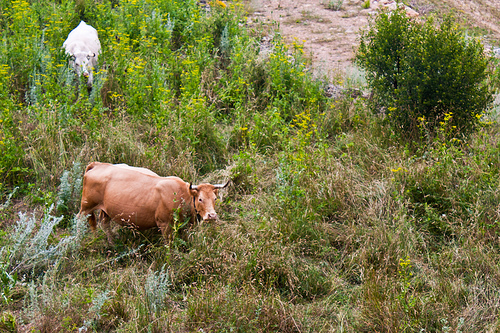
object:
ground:
[282, 1, 498, 89]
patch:
[350, 182, 422, 259]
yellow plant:
[438, 108, 450, 130]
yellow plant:
[382, 103, 394, 121]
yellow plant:
[283, 108, 320, 136]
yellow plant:
[388, 256, 415, 272]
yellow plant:
[115, 28, 147, 72]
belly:
[96, 199, 156, 230]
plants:
[4, 205, 67, 275]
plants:
[18, 266, 59, 328]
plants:
[56, 163, 82, 213]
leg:
[97, 210, 117, 246]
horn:
[188, 175, 198, 190]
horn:
[213, 177, 232, 189]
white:
[74, 32, 89, 54]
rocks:
[305, 23, 334, 45]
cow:
[73, 160, 243, 243]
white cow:
[56, 17, 105, 91]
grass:
[291, 146, 443, 248]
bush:
[356, 4, 498, 143]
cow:
[61, 20, 103, 92]